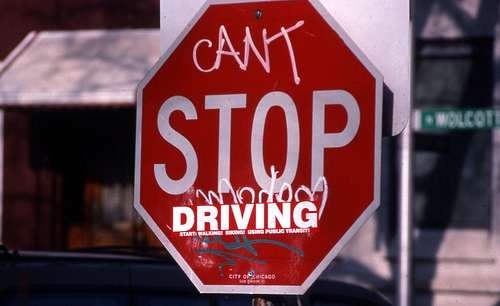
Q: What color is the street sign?
A: Green.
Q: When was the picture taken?
A: Daytime.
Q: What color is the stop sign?
A: Red.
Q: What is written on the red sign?
A: Stop.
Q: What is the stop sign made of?
A: Metal.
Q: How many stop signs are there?
A: One.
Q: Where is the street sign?
A: Behind the stop sign.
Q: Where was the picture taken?
A: At an intersection.